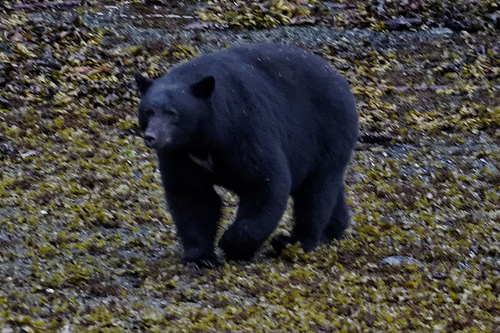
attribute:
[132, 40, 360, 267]
bear — black, large, walking, round, big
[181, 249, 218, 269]
paw — black, large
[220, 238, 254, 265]
paw — lifted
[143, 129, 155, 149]
nose — black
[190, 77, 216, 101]
ear — black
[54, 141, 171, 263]
leaves — green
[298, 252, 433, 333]
leaves — green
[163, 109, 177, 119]
eye — black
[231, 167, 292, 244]
leg — black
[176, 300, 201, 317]
rocks — gray